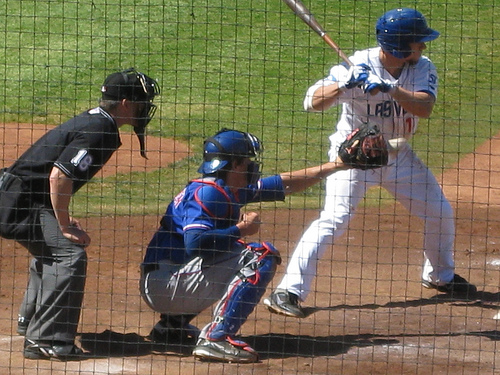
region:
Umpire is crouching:
[2, 47, 149, 362]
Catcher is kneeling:
[133, 117, 308, 352]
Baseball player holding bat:
[272, 0, 490, 316]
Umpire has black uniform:
[1, 67, 151, 358]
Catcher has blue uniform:
[148, 111, 298, 371]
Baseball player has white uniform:
[281, 25, 471, 292]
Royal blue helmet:
[358, 2, 445, 69]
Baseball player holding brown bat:
[261, 0, 402, 110]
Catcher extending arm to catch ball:
[133, 101, 359, 361]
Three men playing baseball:
[1, 7, 496, 357]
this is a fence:
[128, 57, 386, 367]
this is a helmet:
[210, 136, 249, 158]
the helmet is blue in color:
[386, 19, 397, 30]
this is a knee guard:
[259, 239, 285, 261]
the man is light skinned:
[291, 168, 307, 188]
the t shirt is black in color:
[43, 126, 70, 151]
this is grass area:
[169, 0, 288, 93]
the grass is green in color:
[188, 46, 273, 90]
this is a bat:
[287, 4, 357, 56]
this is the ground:
[337, 279, 393, 336]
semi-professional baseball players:
[18, 3, 495, 343]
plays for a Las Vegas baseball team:
[310, 1, 472, 296]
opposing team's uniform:
[165, 116, 275, 363]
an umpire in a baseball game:
[5, 25, 164, 365]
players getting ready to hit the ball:
[291, 3, 429, 285]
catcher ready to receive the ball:
[183, 117, 405, 294]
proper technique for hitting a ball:
[275, 4, 478, 326]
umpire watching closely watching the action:
[60, 57, 460, 278]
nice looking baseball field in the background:
[8, 2, 301, 63]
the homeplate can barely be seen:
[311, 279, 498, 374]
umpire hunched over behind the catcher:
[2, 57, 297, 360]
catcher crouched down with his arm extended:
[142, 113, 400, 370]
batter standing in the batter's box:
[263, 1, 488, 319]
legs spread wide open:
[261, 138, 481, 317]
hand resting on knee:
[58, 214, 95, 256]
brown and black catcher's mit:
[333, 121, 395, 173]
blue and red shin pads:
[208, 239, 291, 341]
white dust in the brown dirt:
[348, 331, 418, 362]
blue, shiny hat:
[179, 114, 267, 174]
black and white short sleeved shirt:
[8, 95, 123, 218]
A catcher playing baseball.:
[136, 122, 389, 364]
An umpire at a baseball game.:
[3, 65, 163, 360]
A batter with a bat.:
[262, 0, 479, 319]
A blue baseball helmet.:
[375, 7, 440, 60]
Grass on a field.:
[2, 2, 499, 217]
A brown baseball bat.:
[283, 0, 380, 95]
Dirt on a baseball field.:
[3, 120, 497, 372]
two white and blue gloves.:
[336, 60, 401, 97]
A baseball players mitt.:
[337, 122, 390, 167]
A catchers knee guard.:
[206, 241, 283, 357]